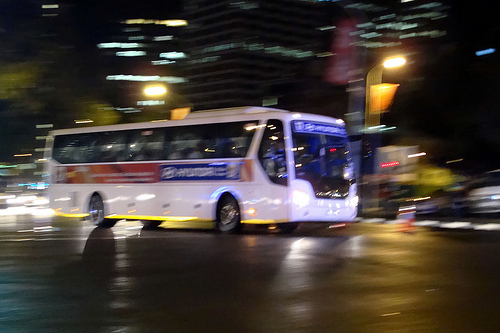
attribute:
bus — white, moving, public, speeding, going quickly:
[42, 105, 360, 237]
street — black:
[1, 215, 499, 331]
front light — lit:
[293, 190, 309, 208]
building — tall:
[179, 3, 345, 123]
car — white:
[454, 169, 499, 217]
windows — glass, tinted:
[54, 120, 259, 165]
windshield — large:
[291, 121, 356, 200]